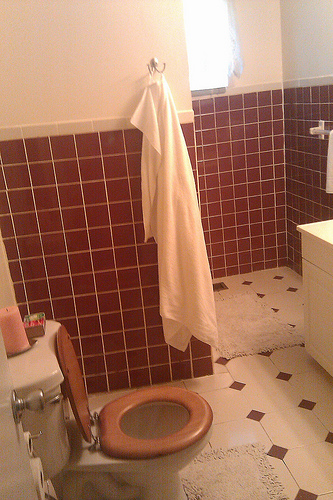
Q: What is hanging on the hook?
A: Towel.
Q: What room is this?
A: Bathroom.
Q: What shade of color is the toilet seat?
A: Brown.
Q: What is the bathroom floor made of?
A: Tile.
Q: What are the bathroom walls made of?
A: Tiles.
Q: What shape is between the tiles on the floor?
A: Diamond.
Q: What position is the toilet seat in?
A: Up.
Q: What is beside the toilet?
A: Toilet paper.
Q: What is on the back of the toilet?
A: Candle.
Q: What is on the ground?
A: Bath mats.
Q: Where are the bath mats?
A: On the ground.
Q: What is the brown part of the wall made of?
A: Tile.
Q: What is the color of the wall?
A: Brown.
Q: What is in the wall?
A: Tiles.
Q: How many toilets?
A: 1.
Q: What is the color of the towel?
A: White.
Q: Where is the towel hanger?
A: In the wall.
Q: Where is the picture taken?
A: In the bathroom.